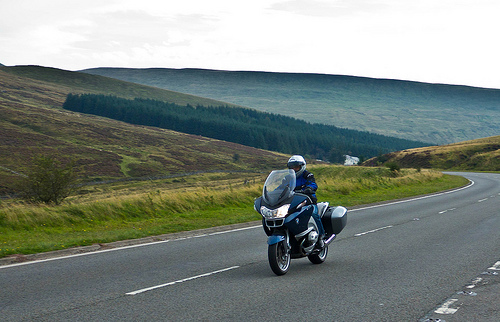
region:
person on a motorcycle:
[246, 150, 353, 286]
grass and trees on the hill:
[3, 60, 470, 256]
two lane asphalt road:
[6, 161, 497, 316]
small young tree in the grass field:
[20, 152, 76, 212]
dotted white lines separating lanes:
[125, 185, 485, 296]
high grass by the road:
[3, 172, 444, 222]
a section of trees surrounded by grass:
[60, 87, 437, 160]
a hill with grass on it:
[355, 125, 496, 170]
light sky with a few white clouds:
[0, 1, 492, 88]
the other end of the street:
[337, 133, 360, 163]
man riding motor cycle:
[221, 140, 366, 281]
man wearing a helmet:
[230, 140, 350, 285]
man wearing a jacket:
[245, 130, 365, 278]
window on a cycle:
[258, 162, 296, 209]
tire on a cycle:
[256, 238, 291, 269]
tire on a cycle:
[316, 233, 332, 265]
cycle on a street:
[261, 170, 312, 275]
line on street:
[111, 252, 251, 297]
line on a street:
[351, 215, 408, 245]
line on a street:
[426, 188, 493, 226]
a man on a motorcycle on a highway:
[250, 150, 350, 278]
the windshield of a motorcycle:
[260, 165, 297, 206]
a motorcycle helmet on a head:
[283, 153, 310, 175]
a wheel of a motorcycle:
[264, 232, 292, 276]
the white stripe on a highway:
[348, 217, 395, 242]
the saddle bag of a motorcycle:
[321, 200, 348, 237]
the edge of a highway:
[17, 227, 168, 267]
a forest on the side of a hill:
[66, 87, 369, 162]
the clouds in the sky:
[3, 4, 215, 57]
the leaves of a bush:
[21, 152, 78, 194]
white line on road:
[118, 263, 243, 299]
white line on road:
[433, 248, 494, 315]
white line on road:
[350, 224, 395, 237]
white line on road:
[435, 203, 460, 217]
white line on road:
[474, 195, 492, 203]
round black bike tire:
[266, 240, 298, 275]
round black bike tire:
[310, 241, 327, 265]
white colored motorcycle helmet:
[286, 151, 305, 173]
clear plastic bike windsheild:
[261, 167, 295, 202]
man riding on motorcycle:
[249, 150, 351, 275]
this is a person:
[232, 147, 355, 286]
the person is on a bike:
[253, 142, 365, 279]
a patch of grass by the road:
[8, 196, 90, 248]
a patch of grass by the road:
[78, 192, 169, 234]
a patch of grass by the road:
[183, 167, 255, 243]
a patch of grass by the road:
[324, 157, 376, 203]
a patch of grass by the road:
[368, 162, 478, 197]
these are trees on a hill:
[176, 98, 227, 135]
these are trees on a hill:
[235, 120, 292, 151]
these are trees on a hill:
[301, 120, 355, 162]